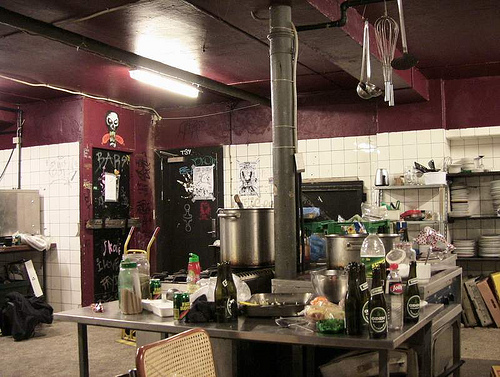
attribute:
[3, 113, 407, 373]
kitchen — dirty, restaurant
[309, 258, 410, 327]
bottles — green, wine, dark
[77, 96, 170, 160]
skull — painted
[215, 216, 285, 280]
pot — large, metal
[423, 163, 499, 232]
shelf — metal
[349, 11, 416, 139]
ladels — hanging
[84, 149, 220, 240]
door — black, covered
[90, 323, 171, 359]
cart — yellow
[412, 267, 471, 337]
oven — silver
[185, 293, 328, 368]
counter — silver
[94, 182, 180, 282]
figure — alien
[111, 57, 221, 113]
lamp — light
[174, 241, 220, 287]
bottle — ketchup, plastic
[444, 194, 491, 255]
plates — stacked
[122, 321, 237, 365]
chair — here, rattan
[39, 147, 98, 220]
wall — tiled, red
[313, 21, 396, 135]
ladles — metallic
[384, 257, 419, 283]
cap — red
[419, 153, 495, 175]
dishes — stacked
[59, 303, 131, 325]
table — metal, stainless, steel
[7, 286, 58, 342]
backpack — black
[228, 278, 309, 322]
pan — steel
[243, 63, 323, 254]
pipe — grey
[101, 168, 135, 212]
paper — taped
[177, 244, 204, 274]
top — green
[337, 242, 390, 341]
bottle — beer